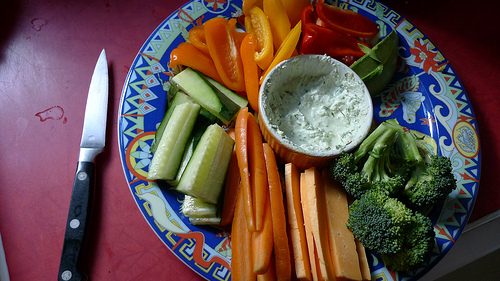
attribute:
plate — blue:
[127, 3, 477, 272]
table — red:
[1, 1, 498, 279]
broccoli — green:
[336, 122, 408, 193]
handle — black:
[39, 161, 134, 253]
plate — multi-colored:
[125, 22, 162, 247]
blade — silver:
[74, 45, 106, 151]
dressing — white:
[316, 92, 326, 109]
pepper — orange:
[235, 24, 263, 114]